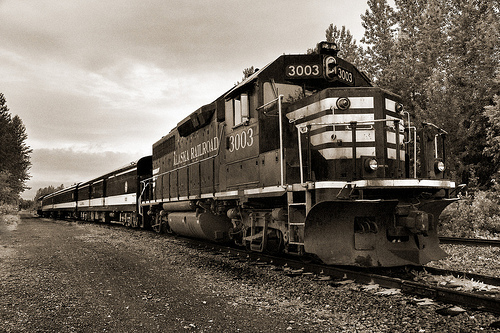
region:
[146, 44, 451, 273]
a black train engine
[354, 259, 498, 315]
a set of train tracks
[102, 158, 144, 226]
a train box car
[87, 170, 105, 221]
a train box car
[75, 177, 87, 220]
a train box car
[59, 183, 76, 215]
a train box car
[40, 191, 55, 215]
a train box car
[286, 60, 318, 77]
a train identification number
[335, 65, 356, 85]
a train identification number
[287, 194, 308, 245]
a short ladder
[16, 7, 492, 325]
the black and white photograph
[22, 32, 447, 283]
the train on the tracks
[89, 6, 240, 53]
clouds in the sky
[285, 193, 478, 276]
a plow on the train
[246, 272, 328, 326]
gravel beside the track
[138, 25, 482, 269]
the locomotive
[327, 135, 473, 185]
the lights on the train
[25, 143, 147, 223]
the cabins of the train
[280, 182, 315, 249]
small ladder on the train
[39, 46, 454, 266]
a train on the tracks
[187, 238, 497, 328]
a set of train tracks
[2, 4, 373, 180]
a cloudy sky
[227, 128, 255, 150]
the number "3003" on the side of a train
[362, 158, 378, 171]
a headlight on the front of a train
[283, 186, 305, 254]
a step ladder on the side of a train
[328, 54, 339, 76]
a signal light on the front of a train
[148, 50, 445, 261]
the front car of a train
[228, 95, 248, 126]
a window on the side of a train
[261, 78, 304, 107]
a window on front of a train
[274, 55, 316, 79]
3003 number is in white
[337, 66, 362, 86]
3003 number is in white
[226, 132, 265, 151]
3003 number is in white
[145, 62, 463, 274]
the train is black and white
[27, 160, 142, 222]
the train carts are six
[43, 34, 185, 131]
clouds are in the sky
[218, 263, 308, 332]
gravel is on the train tracks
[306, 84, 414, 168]
the strips are white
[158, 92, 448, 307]
the train is mettalic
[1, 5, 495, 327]
the photo is black and white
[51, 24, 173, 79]
this is the sky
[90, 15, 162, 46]
the sky has some clouds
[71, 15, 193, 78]
the clouds are white in color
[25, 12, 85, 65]
the sky is bright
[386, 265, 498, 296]
this is a railway line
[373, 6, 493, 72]
this is a tree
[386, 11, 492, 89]
the tree has some leaves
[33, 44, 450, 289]
this is a train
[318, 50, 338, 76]
this is a headlight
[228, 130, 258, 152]
these are four digits